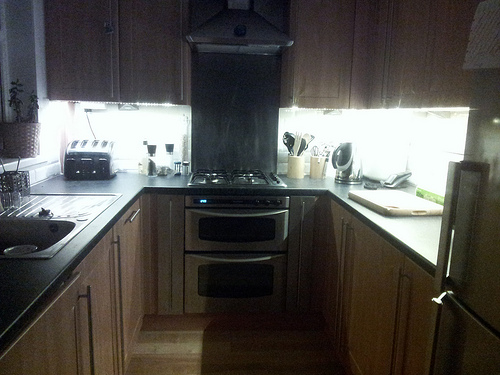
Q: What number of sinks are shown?
A: One.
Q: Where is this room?
A: The kitchen.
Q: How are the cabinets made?
A: Of wood.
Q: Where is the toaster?
A: The counter.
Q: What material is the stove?
A: Stainless steel.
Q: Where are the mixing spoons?
A: A wooden canister.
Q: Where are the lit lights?
A: Under the cabinets.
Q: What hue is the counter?
A: Black.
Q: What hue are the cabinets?
A: Brown.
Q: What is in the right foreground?
A: A fridge.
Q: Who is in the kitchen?
A: No one.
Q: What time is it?
A: Afternoon.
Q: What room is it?
A: Kitchen.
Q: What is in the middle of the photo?
A: An oven.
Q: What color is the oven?
A: Silver.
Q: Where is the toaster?
A: On the left.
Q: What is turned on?
A: Light.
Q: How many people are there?
A: None.